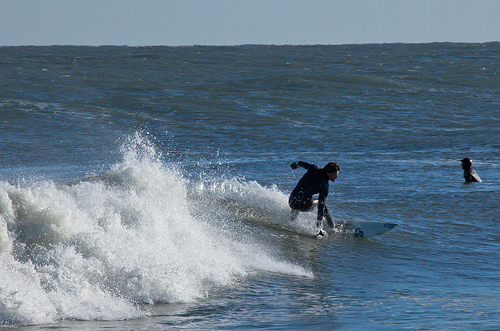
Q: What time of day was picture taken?
A: Daytime.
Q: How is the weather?
A: Clear blue skies.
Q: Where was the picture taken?
A: At the beach.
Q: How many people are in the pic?
A: Two.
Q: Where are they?
A: In the ocean.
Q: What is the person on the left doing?
A: Surfing.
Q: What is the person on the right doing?
A: Swimming.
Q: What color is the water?
A: Blue.